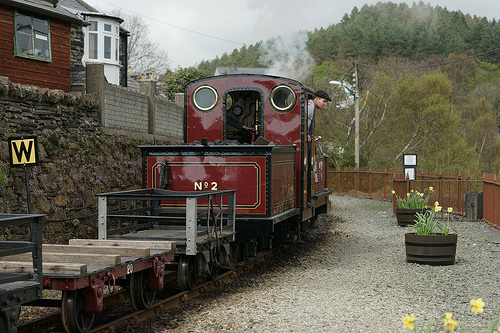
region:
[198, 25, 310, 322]
a train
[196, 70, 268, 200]
a train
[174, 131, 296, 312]
a train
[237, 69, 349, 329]
a train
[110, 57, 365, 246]
red train engine on track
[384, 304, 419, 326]
yellow daffodil in planter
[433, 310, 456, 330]
yellow daffodil in planter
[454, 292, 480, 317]
yellow daffodil in planter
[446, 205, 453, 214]
yellow daffodil in planter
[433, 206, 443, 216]
yellow daffodil in planter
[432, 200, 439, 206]
yellow daffodil in planter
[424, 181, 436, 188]
yellow daffodil in planter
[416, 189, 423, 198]
yellow daffodil in planter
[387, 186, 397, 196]
yellow daffodil in planter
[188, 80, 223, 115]
a window on the train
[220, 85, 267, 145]
the door of a train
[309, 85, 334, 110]
the head of a man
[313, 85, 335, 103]
a black hat of a man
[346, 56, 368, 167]
a brown wooden pole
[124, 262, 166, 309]
a metal train wheel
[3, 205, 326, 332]
a set of train tracks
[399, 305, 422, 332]
a yellow flower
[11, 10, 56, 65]
a window on the building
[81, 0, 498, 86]
a cloudy gray sky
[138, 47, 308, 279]
red train on the railroad tracks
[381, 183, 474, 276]
flowers in planters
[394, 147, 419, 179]
white sign with black frame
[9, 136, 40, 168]
yellow sign with black W on it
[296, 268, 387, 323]
gravel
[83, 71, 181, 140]
block barrier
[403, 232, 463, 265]
brown wooden planter with two black stripes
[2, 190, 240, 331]
cars of a train on railroad tracks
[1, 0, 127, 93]
red and white house with windows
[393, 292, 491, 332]
three yellow flower blooms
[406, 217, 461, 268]
Wooden planter on the ground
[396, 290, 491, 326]
Yellow flowers growing out of pot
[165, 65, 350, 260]
Red and black train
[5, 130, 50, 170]
Yellow and black sign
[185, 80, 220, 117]
Round window on back of train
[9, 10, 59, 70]
Window on side of building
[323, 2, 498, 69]
Pine trees on top of hill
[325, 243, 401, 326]
Gravel path parking area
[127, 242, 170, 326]
Rusty wheels on train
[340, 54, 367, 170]
Wood pole holding up line